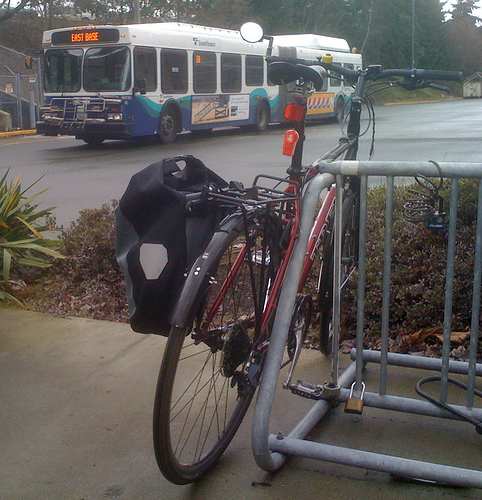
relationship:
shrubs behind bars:
[54, 195, 122, 285] [250, 158, 479, 487]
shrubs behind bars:
[365, 177, 479, 335] [250, 158, 479, 487]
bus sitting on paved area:
[32, 23, 364, 125] [27, 146, 134, 174]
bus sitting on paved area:
[32, 23, 364, 125] [205, 134, 273, 160]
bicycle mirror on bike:
[237, 18, 263, 45] [127, 50, 454, 421]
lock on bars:
[345, 379, 366, 410] [250, 158, 479, 487]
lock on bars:
[425, 197, 443, 227] [250, 158, 479, 487]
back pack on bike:
[113, 153, 229, 338] [197, 161, 285, 382]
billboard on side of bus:
[187, 92, 259, 126] [33, 10, 362, 144]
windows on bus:
[188, 40, 219, 104] [33, 10, 362, 144]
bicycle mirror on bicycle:
[237, 18, 263, 45] [110, 48, 463, 487]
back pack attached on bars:
[101, 149, 205, 328] [250, 158, 479, 487]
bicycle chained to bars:
[116, 47, 464, 418] [250, 158, 479, 487]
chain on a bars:
[258, 298, 353, 391] [250, 158, 479, 487]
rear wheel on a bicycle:
[152, 197, 289, 484] [110, 48, 463, 487]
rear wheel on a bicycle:
[152, 197, 289, 484] [146, 16, 464, 494]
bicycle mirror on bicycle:
[237, 18, 263, 45] [146, 16, 464, 494]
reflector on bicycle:
[286, 104, 301, 121] [144, 52, 462, 476]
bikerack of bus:
[43, 90, 107, 138] [33, 10, 362, 144]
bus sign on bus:
[69, 31, 98, 42] [33, 10, 362, 144]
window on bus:
[80, 41, 132, 93] [33, 10, 362, 144]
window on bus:
[193, 50, 215, 93] [33, 10, 362, 144]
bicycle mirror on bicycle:
[237, 18, 263, 45] [151, 22, 464, 486]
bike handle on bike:
[261, 59, 469, 91] [156, 22, 474, 495]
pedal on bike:
[282, 355, 321, 408] [156, 22, 474, 495]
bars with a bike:
[250, 158, 479, 487] [106, 99, 459, 344]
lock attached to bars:
[345, 379, 366, 414] [250, 158, 479, 487]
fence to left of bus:
[1, 70, 40, 131] [33, 10, 362, 144]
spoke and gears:
[175, 339, 239, 362] [223, 323, 250, 371]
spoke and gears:
[171, 347, 221, 412] [223, 323, 250, 371]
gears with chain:
[223, 323, 250, 371] [219, 310, 267, 378]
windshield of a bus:
[43, 48, 129, 92] [33, 10, 362, 144]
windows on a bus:
[132, 43, 266, 102] [32, 23, 364, 125]